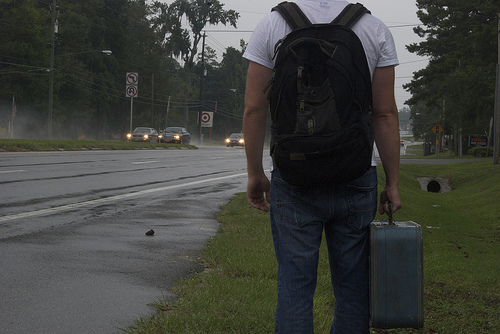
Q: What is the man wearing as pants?
A: A pair of blue jeans.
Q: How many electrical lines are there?
A: Three lines in a row.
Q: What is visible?
A: Back of white shirt.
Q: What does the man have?
A: A suitcase.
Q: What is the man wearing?
A: Backpack.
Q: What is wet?
A: Road.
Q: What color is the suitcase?
A: Blue.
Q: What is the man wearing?
A: Jeans.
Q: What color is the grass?
A: Green.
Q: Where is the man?
A: Outside somewhere.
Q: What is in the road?
A: Cars.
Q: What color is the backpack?
A: Black.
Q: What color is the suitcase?
A: Blue.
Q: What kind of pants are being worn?
A: Jeans.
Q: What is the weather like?
A: Rainy.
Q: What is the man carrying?
A: Luggage.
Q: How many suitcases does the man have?
A: 1.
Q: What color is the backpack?
A: Black.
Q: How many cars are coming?
A: 3.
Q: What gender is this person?
A: Male.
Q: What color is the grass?
A: Green.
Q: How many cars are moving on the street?
A: 3.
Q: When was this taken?
A: During the day.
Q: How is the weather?
A: Overcast and raining.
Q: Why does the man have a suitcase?
A: He is travelling.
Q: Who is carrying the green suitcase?
A: The man.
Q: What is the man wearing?
A: Jeans and a t-shirt.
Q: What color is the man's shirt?
A: White.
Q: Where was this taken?
A: On the side of a road.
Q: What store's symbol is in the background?
A: Target.